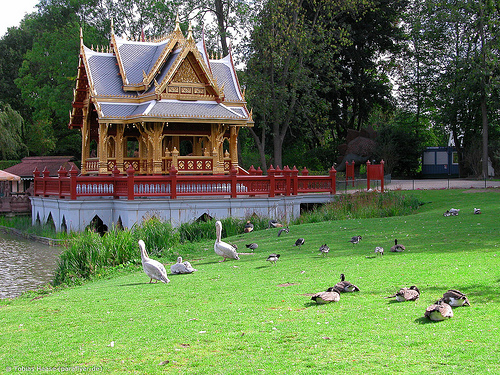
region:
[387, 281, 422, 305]
Duck sitting on grass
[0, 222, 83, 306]
Body of gray water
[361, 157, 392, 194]
Fence painted red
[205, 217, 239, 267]
Duck standing on the grass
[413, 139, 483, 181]
Small blue building in background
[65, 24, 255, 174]
House like structure painted gold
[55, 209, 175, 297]
Plants on edge of water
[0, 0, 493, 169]
Tall trees in the background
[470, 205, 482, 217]
Duck sitting on grass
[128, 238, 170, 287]
Duck standing on grass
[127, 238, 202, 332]
Large white duck in grassy area.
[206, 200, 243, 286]
Large white duck in grassy area.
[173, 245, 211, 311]
Large white duck sitting in grass.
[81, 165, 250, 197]
Red fencing around gazebo.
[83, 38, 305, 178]
Pointed roof on gazebo.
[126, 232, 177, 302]
Large duck in grassy area.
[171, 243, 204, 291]
Large duck sitting on ground.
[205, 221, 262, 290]
Large duck in grassy area.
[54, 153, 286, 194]
Red railing around gazebo.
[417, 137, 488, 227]
Blue building in distance.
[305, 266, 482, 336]
ducks resting on green grass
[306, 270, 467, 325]
ducks laying down in the grass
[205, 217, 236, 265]
a white pelican standing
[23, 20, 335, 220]
Asian looking gazebo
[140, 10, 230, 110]
ornanted gazebo top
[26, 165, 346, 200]
red ornanted fencing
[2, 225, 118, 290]
reeds next to the waters edge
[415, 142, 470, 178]
small blue and white building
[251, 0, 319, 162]
green leaved tree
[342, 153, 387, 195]
red gazebo entrance signs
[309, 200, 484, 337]
the birds are relaxing on the ground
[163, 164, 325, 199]
the fence is red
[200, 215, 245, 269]
the bird has long beaks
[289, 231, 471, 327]
the birds are grey and white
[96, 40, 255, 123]
the roof is grey and white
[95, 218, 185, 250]
tall grass is on the shore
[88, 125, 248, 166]
the columns are golden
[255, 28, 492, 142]
trees are in the background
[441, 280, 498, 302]
shadow is on the grass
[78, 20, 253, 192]
the house has a chinese theme